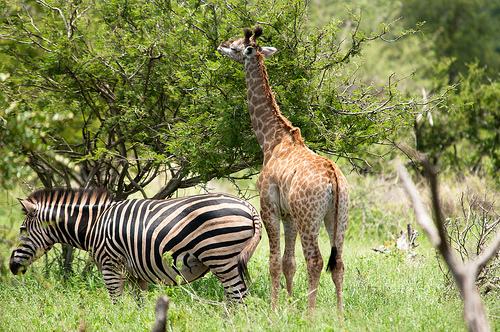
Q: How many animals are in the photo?
A: 2.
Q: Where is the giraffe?
A: Next to the zebra.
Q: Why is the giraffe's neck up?
A: Reaching for vegetation.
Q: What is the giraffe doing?
A: Eating vegetation.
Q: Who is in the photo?
A: No one.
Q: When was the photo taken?
A: Day time.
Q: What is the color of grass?
A: Green.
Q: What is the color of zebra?
A: Black and white.